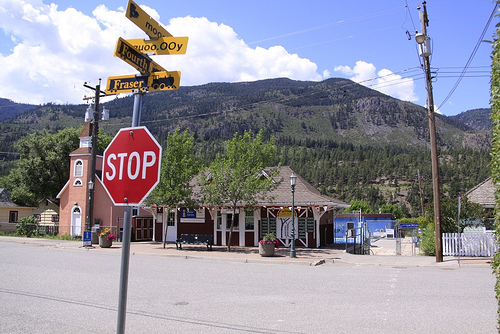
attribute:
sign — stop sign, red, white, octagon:
[101, 125, 164, 206]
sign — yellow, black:
[126, 1, 174, 43]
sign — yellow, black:
[126, 37, 188, 54]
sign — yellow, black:
[114, 36, 167, 73]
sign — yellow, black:
[106, 70, 180, 94]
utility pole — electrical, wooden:
[414, 0, 443, 263]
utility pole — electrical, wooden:
[83, 77, 119, 230]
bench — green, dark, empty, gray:
[173, 233, 214, 250]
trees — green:
[144, 124, 284, 254]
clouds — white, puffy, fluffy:
[0, 0, 442, 114]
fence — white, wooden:
[439, 230, 500, 257]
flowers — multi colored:
[101, 228, 116, 241]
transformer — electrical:
[416, 34, 433, 57]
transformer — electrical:
[84, 105, 94, 124]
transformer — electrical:
[100, 104, 110, 121]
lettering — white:
[106, 151, 157, 181]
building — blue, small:
[334, 208, 396, 239]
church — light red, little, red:
[55, 123, 155, 241]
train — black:
[151, 73, 174, 90]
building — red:
[143, 166, 351, 248]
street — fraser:
[1, 235, 500, 331]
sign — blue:
[82, 229, 93, 246]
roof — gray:
[152, 154, 351, 207]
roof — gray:
[456, 169, 499, 209]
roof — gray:
[0, 186, 59, 208]